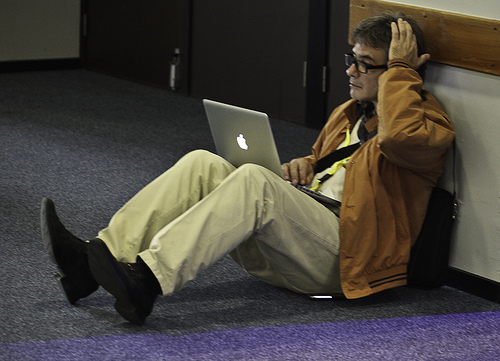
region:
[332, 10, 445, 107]
A man wearing glasses.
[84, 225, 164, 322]
a left black shoe.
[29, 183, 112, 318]
a right black shoe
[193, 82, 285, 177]
an open laptop computer.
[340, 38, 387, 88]
a pair of dark glasses.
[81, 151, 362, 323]
a pair of brown pants.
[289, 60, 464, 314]
an orange jacket.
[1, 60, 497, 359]
a carpet in a room.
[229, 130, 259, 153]
an apple on a computer.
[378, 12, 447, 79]
a human hand.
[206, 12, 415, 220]
a man is using laptop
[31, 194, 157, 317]
a man wearing black color shoes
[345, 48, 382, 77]
a man wearing eyeglasses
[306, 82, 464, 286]
a man holding laptop bag in his shoulders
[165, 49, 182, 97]
silver handle of the wardrobe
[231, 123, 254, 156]
apple inc symbol in front of the laptop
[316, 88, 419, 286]
a man wearing orange color jacket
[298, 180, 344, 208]
a person ID card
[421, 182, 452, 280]
black color laptop bag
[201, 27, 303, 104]
a grey color wardrobe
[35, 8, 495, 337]
the man is sitting on the floor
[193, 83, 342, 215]
a silver apple laptop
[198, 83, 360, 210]
a silver MacBook pro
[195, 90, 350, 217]
a Macbook is on his lap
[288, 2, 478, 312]
he is wearing an orange jacket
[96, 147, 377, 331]
he is wearing off white pants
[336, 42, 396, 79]
he has a black pair of glasses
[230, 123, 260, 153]
the logo is lit up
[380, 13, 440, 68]
his hand is on his head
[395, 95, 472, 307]
his bag is still strapped to himself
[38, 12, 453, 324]
A man is sitting on the floor.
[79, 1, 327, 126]
A doorway with bottom lock near middle.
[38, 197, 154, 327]
Feet wearing black shoes.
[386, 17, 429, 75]
Hand on dark hair.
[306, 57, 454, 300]
Man wearing orange jacket.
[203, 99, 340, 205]
Laptop has apple on silver surface.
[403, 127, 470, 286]
Black bag is behind orange fabric.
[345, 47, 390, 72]
A man is wearing glasses.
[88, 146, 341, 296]
White pants on two legs.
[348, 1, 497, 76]
Head next to wooden board.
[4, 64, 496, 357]
A grey colored floor.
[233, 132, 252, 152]
A white apple logo.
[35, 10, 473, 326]
A man sitting on the ground, leaned against a wall.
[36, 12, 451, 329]
A man looking at his laptop.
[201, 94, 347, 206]
A silver and white laptop.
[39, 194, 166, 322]
A pair of black loafers.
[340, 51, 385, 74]
A black framed pair of glasses.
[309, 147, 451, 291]
A black messenger bag with a black strap.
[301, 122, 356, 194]
A yellow and black lanyard.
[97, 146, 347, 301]
A pair of khaki slacks.